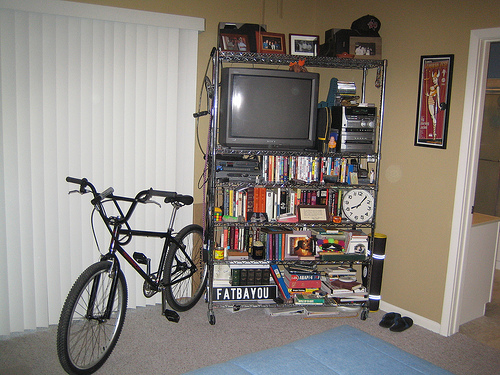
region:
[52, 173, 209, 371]
A black framed bicycle.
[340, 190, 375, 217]
A round white clock.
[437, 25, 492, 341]
A white door frame.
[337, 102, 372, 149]
A black and silver stereo.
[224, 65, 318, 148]
A grey television.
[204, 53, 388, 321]
A silver metal stand on wheels.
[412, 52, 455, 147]
A black framed picture.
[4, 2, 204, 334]
Long white blinds.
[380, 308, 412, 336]
A dark pair of flip-flops.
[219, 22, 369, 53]
Black and silver stereo speakers.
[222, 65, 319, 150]
a grey framed TV set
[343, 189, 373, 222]
a white and black face clock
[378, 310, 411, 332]
a pair of black slippers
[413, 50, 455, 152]
a black framed print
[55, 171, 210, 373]
a black bicycle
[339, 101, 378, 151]
a silver stereo set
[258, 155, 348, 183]
a shelf of DVDs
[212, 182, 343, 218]
a shelf of books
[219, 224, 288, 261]
a shelf of books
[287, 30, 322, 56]
a black framed photo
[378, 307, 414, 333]
black flip flops on a carpet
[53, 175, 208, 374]
black bicycle on a carpet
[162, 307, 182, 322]
black peddle on a bicycle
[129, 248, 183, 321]
two black bicycle peddles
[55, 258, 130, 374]
large bicycle wheel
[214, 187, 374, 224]
shelf packed with lots of different objects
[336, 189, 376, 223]
black and white clock on a shelf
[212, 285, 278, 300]
black and white sign on a shelf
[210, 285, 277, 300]
black and white sign on a shelf reading FATBAYOU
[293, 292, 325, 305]
green and white books on a shelf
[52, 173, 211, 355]
black bike by white blinds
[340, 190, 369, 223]
clock on shelf of bookcase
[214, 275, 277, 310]
black sign with white lettering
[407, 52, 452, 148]
painting with red background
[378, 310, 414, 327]
black shoes next to wall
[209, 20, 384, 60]
picture frames on top shelf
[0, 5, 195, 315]
vertical blinds covering window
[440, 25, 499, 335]
white doorframe of door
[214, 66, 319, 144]
black tv on second shelf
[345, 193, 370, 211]
big hand and small hand of clock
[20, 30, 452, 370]
A bicycle is in a room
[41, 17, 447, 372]
A television set is on a shelf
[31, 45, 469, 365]
A clock is in a room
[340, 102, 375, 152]
The front of a stereo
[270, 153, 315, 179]
Books that are on a shelf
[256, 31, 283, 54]
A picture on a shelf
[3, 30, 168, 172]
Curtains covering a window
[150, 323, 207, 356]
Some carpet in a room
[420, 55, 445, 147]
A picture hanging on a wall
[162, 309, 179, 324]
A pedal on a bicycle